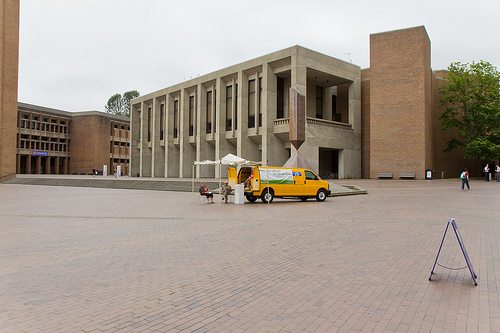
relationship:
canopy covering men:
[189, 150, 266, 205] [197, 180, 211, 203]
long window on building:
[248, 72, 265, 134] [127, 45, 362, 177]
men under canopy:
[199, 180, 216, 204] [191, 152, 262, 206]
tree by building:
[439, 68, 498, 177] [355, 28, 451, 193]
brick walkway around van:
[0, 177, 498, 331] [232, 163, 332, 204]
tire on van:
[260, 188, 274, 204] [241, 150, 336, 203]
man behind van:
[220, 181, 232, 204] [223, 162, 332, 202]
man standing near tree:
[483, 164, 490, 183] [434, 59, 499, 174]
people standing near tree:
[495, 162, 499, 177] [434, 59, 499, 174]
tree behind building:
[106, 91, 138, 116] [18, 101, 127, 173]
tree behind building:
[106, 91, 138, 116] [127, 45, 362, 177]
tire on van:
[260, 188, 274, 204] [227, 161, 338, 201]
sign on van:
[264, 166, 292, 184] [207, 149, 359, 206]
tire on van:
[314, 184, 328, 206] [204, 129, 359, 217]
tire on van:
[262, 188, 278, 205] [204, 129, 359, 217]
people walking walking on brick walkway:
[439, 153, 497, 192] [0, 173, 500, 333]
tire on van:
[316, 189, 327, 202] [230, 157, 331, 207]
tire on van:
[260, 188, 274, 204] [230, 157, 331, 207]